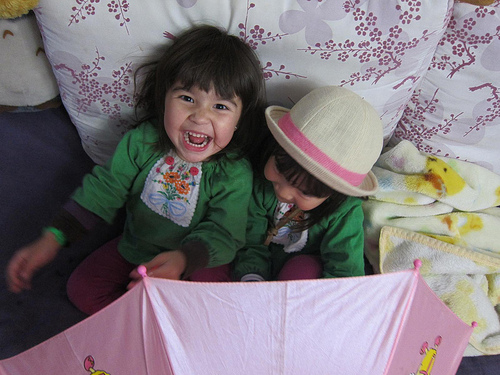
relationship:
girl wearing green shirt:
[0, 27, 261, 316] [47, 120, 254, 280]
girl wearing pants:
[0, 27, 261, 316] [67, 236, 233, 315]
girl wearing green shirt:
[192, 85, 377, 293] [234, 169, 368, 280]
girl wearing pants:
[192, 85, 377, 293] [276, 251, 322, 279]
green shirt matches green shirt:
[47, 120, 254, 280] [234, 169, 368, 280]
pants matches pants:
[67, 236, 233, 315] [276, 251, 322, 279]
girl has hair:
[0, 27, 261, 316] [135, 17, 276, 142]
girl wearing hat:
[192, 85, 377, 293] [258, 87, 380, 190]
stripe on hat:
[276, 109, 367, 187] [258, 87, 380, 190]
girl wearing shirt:
[192, 85, 377, 293] [230, 174, 367, 282]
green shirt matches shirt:
[47, 120, 254, 280] [230, 174, 367, 282]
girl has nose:
[0, 27, 261, 316] [189, 102, 209, 123]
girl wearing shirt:
[0, 27, 261, 316] [105, 127, 275, 265]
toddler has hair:
[37, 120, 254, 318] [132, 23, 259, 163]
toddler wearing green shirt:
[4, 15, 272, 305] [47, 120, 254, 280]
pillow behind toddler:
[25, 12, 442, 162] [4, 15, 272, 305]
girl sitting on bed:
[192, 85, 377, 293] [1, 0, 499, 373]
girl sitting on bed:
[0, 27, 261, 316] [1, 0, 499, 373]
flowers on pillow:
[428, 6, 499, 79] [384, 4, 499, 174]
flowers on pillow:
[465, 79, 499, 135] [384, 4, 499, 174]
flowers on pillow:
[388, 86, 465, 157] [384, 4, 499, 174]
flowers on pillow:
[298, 1, 438, 89] [25, 0, 455, 169]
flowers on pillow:
[233, 2, 310, 82] [25, 0, 455, 169]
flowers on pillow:
[49, 46, 136, 126] [25, 0, 455, 169]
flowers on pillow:
[64, 0, 134, 38] [25, 0, 455, 169]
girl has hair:
[0, 27, 261, 316] [153, 19, 270, 161]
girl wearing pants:
[0, 27, 261, 316] [93, 223, 268, 298]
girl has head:
[76, 27, 261, 294] [143, 15, 267, 177]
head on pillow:
[143, 15, 267, 177] [37, 1, 441, 148]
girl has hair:
[192, 85, 377, 293] [292, 168, 339, 226]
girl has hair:
[0, 27, 261, 316] [149, 30, 250, 85]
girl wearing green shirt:
[0, 27, 261, 316] [58, 149, 248, 253]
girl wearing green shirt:
[239, 85, 370, 277] [241, 169, 363, 278]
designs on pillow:
[333, 17, 435, 89] [25, 0, 455, 169]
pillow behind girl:
[25, 0, 455, 169] [192, 85, 377, 293]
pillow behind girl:
[25, 0, 455, 169] [0, 27, 261, 316]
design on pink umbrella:
[403, 333, 456, 370] [0, 261, 477, 374]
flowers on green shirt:
[147, 154, 198, 219] [47, 120, 254, 280]